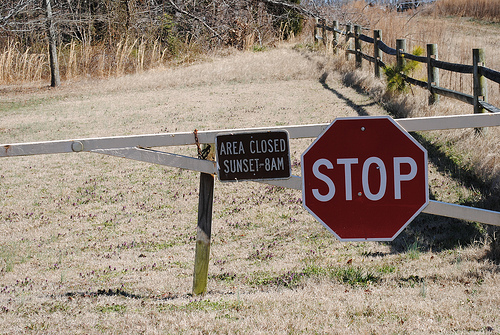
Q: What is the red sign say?
A: Stop.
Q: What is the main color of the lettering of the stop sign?
A: White.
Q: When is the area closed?
A: Sunset-8am.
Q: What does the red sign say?
A: Stop.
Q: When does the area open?
A: 8am.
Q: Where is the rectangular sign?
A: Gate.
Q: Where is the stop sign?
A: Gate.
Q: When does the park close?
A: Sunset.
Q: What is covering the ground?
A: Grass.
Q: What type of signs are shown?
A: Closed and stop.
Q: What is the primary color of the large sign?
A: Red.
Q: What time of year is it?
A: Autumn.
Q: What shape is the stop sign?
A: Octagon.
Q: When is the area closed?
A: Sunset to 8AM.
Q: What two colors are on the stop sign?
A: Red and white.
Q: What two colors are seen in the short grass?
A: Beige and green.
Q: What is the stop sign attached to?
A: A white gate.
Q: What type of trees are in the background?
A: Deciduous.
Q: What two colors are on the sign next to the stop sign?
A: Brown and white.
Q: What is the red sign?
A: Stop.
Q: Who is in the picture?
A: No one.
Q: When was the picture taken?
A: Day time.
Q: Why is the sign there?
A: To make people stop.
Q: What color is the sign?
A: White and red.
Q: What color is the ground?
A: Brown.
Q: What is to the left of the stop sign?
A: Another sign.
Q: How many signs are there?
A: Two.